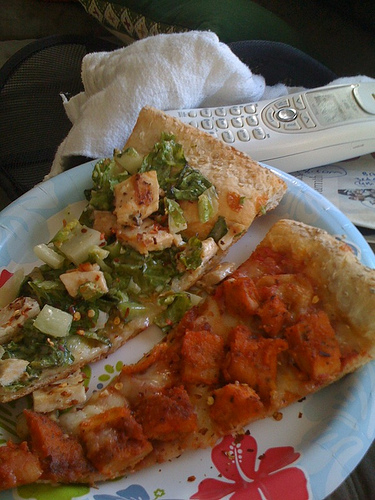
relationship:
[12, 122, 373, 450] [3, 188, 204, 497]
pizza on plate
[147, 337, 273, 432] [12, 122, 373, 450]
meat on pizza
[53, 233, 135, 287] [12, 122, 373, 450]
vegetable on pizza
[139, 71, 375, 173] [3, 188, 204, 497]
phone beside plate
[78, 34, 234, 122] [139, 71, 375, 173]
cloth beside phone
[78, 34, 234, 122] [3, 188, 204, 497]
cloth beside plate